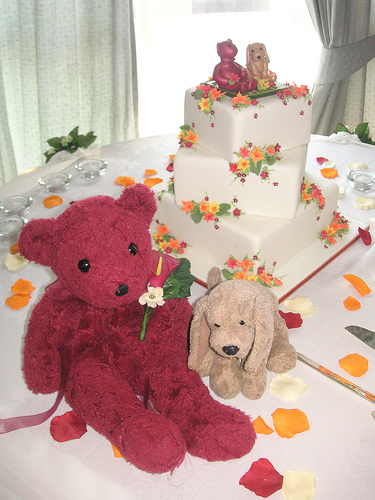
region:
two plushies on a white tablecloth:
[20, 181, 298, 474]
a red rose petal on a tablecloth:
[239, 458, 285, 498]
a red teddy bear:
[16, 182, 254, 473]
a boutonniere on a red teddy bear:
[139, 257, 194, 337]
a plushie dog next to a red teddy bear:
[185, 278, 297, 398]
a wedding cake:
[149, 39, 370, 304]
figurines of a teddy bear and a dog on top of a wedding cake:
[215, 39, 278, 94]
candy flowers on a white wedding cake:
[229, 140, 281, 192]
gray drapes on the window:
[2, 2, 373, 183]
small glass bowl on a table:
[1, 156, 107, 215]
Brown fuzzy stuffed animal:
[188, 266, 300, 401]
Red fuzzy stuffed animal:
[19, 181, 258, 468]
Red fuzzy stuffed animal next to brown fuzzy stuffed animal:
[17, 182, 296, 473]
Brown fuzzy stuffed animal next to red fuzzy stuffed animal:
[19, 181, 299, 476]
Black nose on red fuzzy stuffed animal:
[113, 283, 127, 296]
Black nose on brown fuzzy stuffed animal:
[222, 343, 239, 356]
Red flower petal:
[239, 456, 282, 497]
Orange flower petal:
[270, 405, 311, 438]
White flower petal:
[282, 292, 317, 317]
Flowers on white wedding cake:
[152, 77, 341, 281]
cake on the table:
[142, 33, 368, 322]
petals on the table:
[258, 263, 373, 491]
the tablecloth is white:
[315, 391, 361, 491]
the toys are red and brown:
[8, 199, 296, 475]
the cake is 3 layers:
[155, 78, 345, 299]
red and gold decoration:
[202, 36, 294, 115]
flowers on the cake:
[136, 120, 361, 311]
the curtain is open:
[299, 3, 368, 144]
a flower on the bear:
[125, 220, 187, 341]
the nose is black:
[212, 340, 256, 366]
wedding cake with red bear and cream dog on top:
[153, 37, 372, 313]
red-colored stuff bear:
[16, 178, 258, 476]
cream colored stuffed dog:
[186, 263, 297, 401]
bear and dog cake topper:
[209, 37, 293, 99]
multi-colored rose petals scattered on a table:
[235, 368, 319, 498]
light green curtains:
[0, 0, 145, 186]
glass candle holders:
[0, 155, 111, 240]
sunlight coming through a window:
[136, 0, 324, 137]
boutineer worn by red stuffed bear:
[133, 255, 169, 341]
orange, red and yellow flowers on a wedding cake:
[175, 189, 246, 229]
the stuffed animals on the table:
[16, 183, 295, 472]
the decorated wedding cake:
[135, 35, 374, 305]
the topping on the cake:
[212, 37, 274, 94]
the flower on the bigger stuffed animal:
[136, 247, 192, 335]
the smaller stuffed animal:
[187, 265, 294, 398]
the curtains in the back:
[2, 1, 373, 140]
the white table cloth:
[5, 131, 374, 489]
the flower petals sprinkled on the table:
[4, 144, 374, 494]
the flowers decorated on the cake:
[149, 75, 357, 283]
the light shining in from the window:
[130, 2, 319, 133]